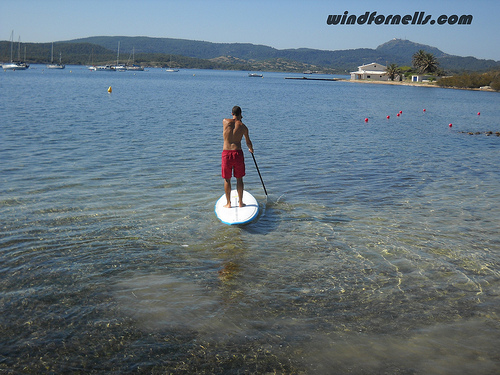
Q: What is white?
A: Surfboard.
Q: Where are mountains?
A: In the distance.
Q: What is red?
A: Man's shorts.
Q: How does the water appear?
A: Calm.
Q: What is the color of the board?
A: White.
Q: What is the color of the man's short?
A: Red.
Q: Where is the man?
A: On the water.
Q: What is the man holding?
A: A paddle.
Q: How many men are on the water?
A: One.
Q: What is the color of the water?
A: Blue.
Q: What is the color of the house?
A: White.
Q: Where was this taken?
A: On the ocean.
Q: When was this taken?
A: During the day.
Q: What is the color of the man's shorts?
A: Red.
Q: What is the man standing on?
A: A paddleboard.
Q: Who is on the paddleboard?
A: The man in red swimming trunks.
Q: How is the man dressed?
A: In red swimming trunks.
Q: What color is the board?
A: White and blue.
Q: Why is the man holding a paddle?
A: To move through the water.